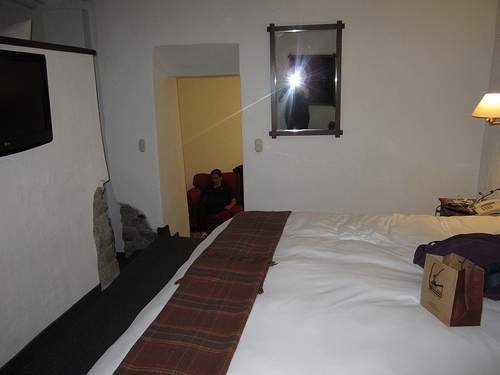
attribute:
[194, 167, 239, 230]
man — sitting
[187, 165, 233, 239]
person — sitting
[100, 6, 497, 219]
wall — white, painted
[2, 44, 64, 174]
tv — black, flat screen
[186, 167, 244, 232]
couch — red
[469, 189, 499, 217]
telephone — white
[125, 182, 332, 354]
blanket — red, plaid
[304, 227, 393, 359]
bedcover — white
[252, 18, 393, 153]
wall — white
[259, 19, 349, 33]
frame — wooden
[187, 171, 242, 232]
sofa — red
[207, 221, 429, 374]
comforter — white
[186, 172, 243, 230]
couch — red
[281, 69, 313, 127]
person — a reflection, reflected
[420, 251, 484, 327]
shopping bag — straw